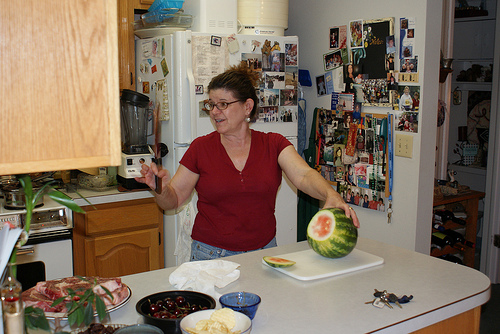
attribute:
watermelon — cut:
[303, 209, 358, 252]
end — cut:
[259, 251, 296, 272]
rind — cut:
[266, 252, 294, 273]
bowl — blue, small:
[223, 293, 261, 312]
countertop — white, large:
[99, 238, 468, 328]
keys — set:
[366, 283, 415, 313]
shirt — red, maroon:
[178, 135, 283, 247]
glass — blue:
[218, 290, 259, 310]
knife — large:
[151, 99, 166, 200]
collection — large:
[302, 19, 421, 205]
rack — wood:
[434, 173, 482, 259]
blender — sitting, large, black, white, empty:
[123, 87, 156, 191]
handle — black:
[155, 158, 163, 192]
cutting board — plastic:
[268, 244, 384, 278]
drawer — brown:
[85, 210, 170, 227]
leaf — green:
[46, 185, 89, 216]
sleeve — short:
[174, 137, 206, 175]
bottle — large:
[438, 208, 463, 227]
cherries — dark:
[155, 294, 203, 317]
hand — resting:
[321, 190, 362, 222]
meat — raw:
[41, 272, 118, 299]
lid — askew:
[120, 86, 158, 106]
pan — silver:
[6, 181, 58, 210]